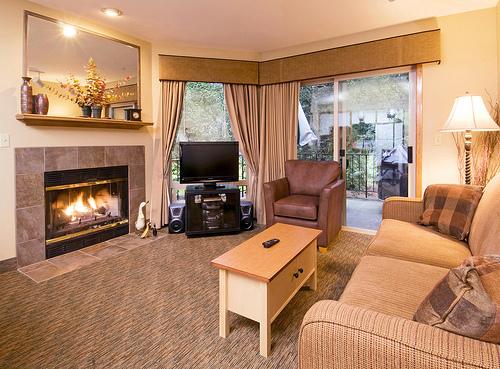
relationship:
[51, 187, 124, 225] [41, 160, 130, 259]
fire lit in a fireplace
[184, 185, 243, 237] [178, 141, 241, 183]
stand holding tv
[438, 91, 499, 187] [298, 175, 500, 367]
lamp sitting beside a sofa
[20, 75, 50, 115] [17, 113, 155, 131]
vases are sitting on a shelf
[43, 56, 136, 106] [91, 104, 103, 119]
flower sitting in a pot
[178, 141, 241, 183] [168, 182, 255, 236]
tv over entertainment center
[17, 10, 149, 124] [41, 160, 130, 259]
mirror hanging over fireplace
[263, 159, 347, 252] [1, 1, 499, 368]
chair sitting in room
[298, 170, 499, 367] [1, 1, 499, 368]
sofa sitting in room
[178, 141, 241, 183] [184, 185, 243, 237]
tv on stand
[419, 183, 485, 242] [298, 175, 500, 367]
pillow sitting on sofa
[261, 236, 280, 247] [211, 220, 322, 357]
control sitting on top of table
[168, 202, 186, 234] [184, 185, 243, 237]
speaker sitting next to stand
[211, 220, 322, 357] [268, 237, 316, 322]
table has a storage area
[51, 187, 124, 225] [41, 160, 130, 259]
fire burning in fireplace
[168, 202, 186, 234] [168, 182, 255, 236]
speaker sitting beside entertainment center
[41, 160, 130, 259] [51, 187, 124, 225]
fireplace has a fire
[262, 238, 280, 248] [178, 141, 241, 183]
control used for tv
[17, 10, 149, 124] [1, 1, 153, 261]
mirror hanging on wall